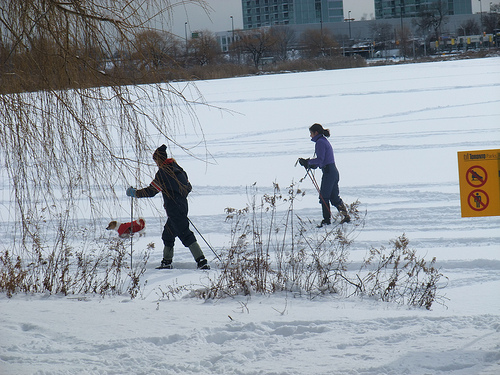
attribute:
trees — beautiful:
[3, 7, 500, 96]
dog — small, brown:
[106, 219, 160, 257]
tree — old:
[1, 2, 246, 247]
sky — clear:
[3, 2, 500, 53]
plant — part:
[218, 193, 276, 298]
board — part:
[456, 149, 499, 218]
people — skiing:
[127, 123, 352, 271]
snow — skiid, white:
[0, 59, 500, 374]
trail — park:
[2, 221, 498, 288]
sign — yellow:
[456, 146, 497, 223]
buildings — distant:
[211, 2, 480, 56]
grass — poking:
[0, 53, 368, 94]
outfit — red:
[119, 220, 143, 238]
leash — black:
[130, 197, 139, 224]